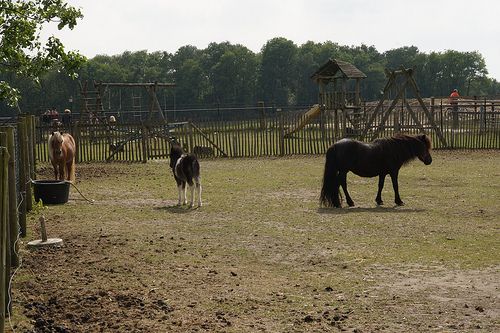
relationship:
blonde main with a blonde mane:
[48, 131, 77, 185] [60, 148, 84, 178]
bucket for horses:
[34, 179, 70, 204] [33, 118, 102, 188]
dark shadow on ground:
[322, 199, 435, 227] [78, 180, 479, 286]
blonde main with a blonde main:
[48, 131, 77, 185] [63, 133, 84, 187]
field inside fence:
[50, 169, 472, 327] [49, 98, 465, 168]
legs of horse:
[167, 168, 237, 225] [168, 142, 238, 228]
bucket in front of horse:
[34, 179, 70, 204] [30, 120, 99, 203]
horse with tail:
[320, 127, 420, 218] [309, 142, 343, 214]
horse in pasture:
[320, 127, 420, 218] [74, 157, 474, 331]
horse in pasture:
[139, 136, 222, 208] [52, 141, 437, 331]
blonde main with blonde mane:
[48, 131, 77, 185] [48, 131, 77, 182]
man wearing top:
[450, 89, 462, 106] [447, 92, 457, 105]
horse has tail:
[318, 134, 433, 207] [314, 134, 348, 225]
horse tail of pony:
[317, 145, 340, 208] [300, 114, 436, 206]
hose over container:
[29, 163, 55, 176] [25, 172, 76, 203]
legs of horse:
[175, 170, 202, 208] [168, 140, 203, 208]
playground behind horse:
[283, 49, 425, 150] [318, 134, 433, 207]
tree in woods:
[425, 41, 498, 117] [251, 43, 456, 111]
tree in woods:
[388, 38, 419, 95] [279, 38, 467, 144]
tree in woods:
[335, 41, 403, 131] [210, 47, 480, 117]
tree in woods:
[335, 41, 388, 103] [259, 43, 485, 154]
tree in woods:
[256, 37, 303, 116] [197, 38, 490, 117]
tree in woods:
[213, 41, 303, 125] [113, 46, 491, 127]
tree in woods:
[104, 47, 195, 117] [73, 39, 306, 117]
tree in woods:
[39, 55, 99, 114] [32, 44, 207, 134]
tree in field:
[31, 46, 93, 146] [14, 109, 357, 209]